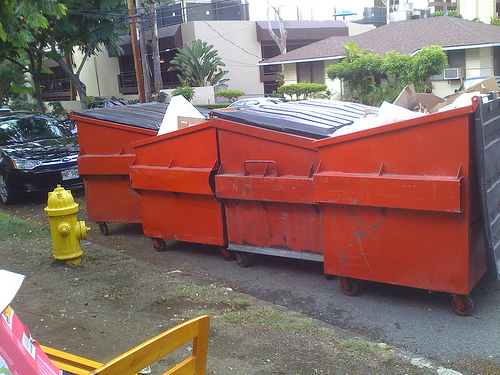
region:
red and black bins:
[65, 77, 447, 293]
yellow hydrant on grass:
[44, 192, 95, 282]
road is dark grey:
[370, 317, 492, 374]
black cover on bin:
[222, 87, 386, 135]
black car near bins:
[0, 97, 75, 202]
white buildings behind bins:
[179, 12, 499, 102]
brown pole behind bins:
[125, 8, 158, 108]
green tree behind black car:
[1, 6, 126, 104]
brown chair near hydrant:
[21, 307, 167, 374]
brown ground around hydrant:
[2, 249, 132, 348]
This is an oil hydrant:
[28, 164, 131, 274]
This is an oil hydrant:
[42, 175, 100, 272]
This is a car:
[2, 110, 109, 207]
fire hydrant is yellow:
[56, 204, 73, 244]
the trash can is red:
[365, 148, 417, 190]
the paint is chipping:
[344, 212, 376, 250]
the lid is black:
[278, 111, 301, 128]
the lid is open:
[437, 88, 497, 131]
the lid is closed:
[106, 110, 143, 133]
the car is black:
[29, 147, 64, 157]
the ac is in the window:
[441, 64, 468, 84]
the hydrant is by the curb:
[66, 221, 119, 258]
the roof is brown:
[416, 23, 440, 35]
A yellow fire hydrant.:
[38, 182, 98, 264]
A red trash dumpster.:
[301, 114, 491, 308]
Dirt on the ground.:
[50, 274, 137, 339]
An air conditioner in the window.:
[435, 58, 468, 85]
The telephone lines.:
[118, 2, 258, 32]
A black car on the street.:
[0, 93, 84, 207]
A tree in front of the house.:
[310, 25, 455, 85]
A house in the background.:
[252, 13, 498, 93]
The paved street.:
[357, 290, 442, 338]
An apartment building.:
[7, 25, 246, 86]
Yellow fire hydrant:
[35, 181, 92, 266]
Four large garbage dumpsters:
[80, 85, 480, 295]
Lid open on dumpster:
[357, 80, 497, 267]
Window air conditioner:
[440, 65, 460, 80]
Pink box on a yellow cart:
[0, 296, 60, 371]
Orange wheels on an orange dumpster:
[330, 267, 483, 318]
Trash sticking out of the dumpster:
[319, 84, 499, 131]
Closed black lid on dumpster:
[209, 94, 404, 145]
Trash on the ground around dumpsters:
[79, 258, 355, 355]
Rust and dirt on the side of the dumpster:
[219, 178, 316, 248]